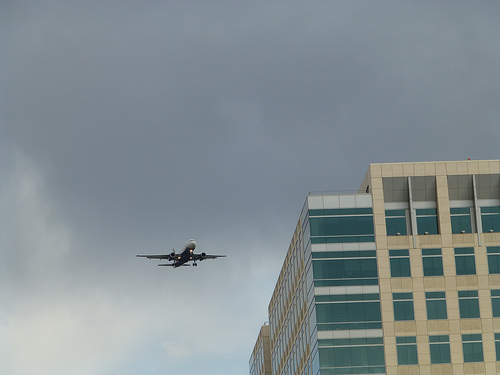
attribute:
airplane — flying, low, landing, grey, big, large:
[135, 238, 229, 270]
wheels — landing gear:
[191, 260, 200, 267]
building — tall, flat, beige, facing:
[243, 158, 500, 374]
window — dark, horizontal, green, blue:
[324, 260, 345, 279]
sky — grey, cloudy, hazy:
[1, 1, 499, 373]